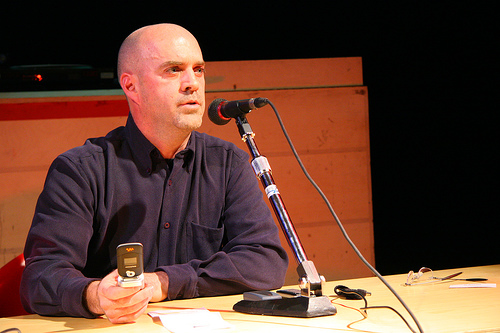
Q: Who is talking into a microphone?
A: A man.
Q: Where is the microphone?
A: On the table.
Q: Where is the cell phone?
A: In the man's hand.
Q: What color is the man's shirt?
A: Purple.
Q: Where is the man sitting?
A: At a table.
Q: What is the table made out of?
A: Wood.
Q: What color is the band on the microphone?
A: Red.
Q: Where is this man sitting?
A: At a microphone.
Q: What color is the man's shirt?
A: Blue.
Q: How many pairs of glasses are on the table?
A: One.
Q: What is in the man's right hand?
A: Phone.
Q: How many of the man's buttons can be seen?
A: Two.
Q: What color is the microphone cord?
A: Black.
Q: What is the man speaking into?
A: Microphone.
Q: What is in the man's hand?
A: Cell phone.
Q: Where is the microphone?
A: In front of the man's face.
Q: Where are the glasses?
A: On the right of the table.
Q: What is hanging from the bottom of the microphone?
A: A cord.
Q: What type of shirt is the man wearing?
A: Button down shirt.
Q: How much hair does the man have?
A: None.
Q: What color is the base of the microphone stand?
A: Black.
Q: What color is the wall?
A: Orange.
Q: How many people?
A: 1.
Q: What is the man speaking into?
A: A microphone.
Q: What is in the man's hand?
A: A cell phone.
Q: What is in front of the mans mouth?
A: A microphone.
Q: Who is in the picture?
A: A man.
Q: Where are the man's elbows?
A: On the table.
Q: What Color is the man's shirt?
A: Black.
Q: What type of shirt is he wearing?
A: A button down.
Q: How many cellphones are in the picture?
A: One.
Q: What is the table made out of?
A: Wood.